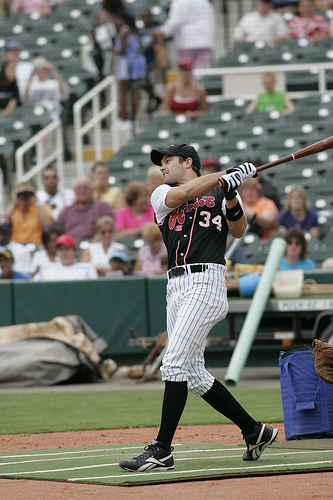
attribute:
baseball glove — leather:
[309, 337, 330, 384]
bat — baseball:
[258, 130, 331, 173]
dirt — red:
[0, 403, 332, 498]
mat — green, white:
[0, 438, 331, 486]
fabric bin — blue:
[272, 330, 331, 446]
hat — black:
[142, 126, 207, 186]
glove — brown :
[306, 336, 332, 379]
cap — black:
[149, 143, 204, 167]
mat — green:
[27, 439, 330, 481]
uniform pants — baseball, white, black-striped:
[156, 263, 231, 394]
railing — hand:
[11, 75, 142, 197]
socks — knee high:
[153, 371, 256, 439]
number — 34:
[200, 204, 221, 232]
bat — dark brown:
[213, 137, 331, 194]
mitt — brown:
[312, 336, 331, 384]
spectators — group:
[3, 3, 332, 282]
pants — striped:
[162, 262, 229, 396]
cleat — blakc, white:
[105, 391, 307, 481]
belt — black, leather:
[155, 257, 232, 276]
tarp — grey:
[7, 312, 107, 392]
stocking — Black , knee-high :
[199, 379, 259, 433]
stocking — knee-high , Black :
[152, 377, 190, 444]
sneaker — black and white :
[241, 419, 279, 462]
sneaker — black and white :
[118, 438, 177, 472]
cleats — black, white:
[118, 419, 277, 475]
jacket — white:
[166, 1, 214, 49]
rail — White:
[71, 72, 122, 179]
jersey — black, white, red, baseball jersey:
[146, 179, 235, 264]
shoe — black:
[117, 440, 177, 475]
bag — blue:
[252, 334, 324, 425]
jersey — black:
[148, 183, 240, 270]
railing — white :
[66, 71, 127, 184]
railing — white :
[11, 116, 68, 209]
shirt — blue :
[236, 254, 322, 296]